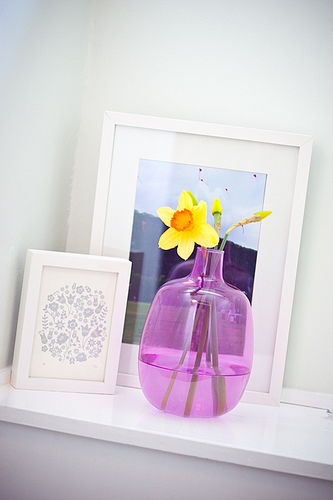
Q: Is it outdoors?
A: Yes, it is outdoors.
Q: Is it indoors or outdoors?
A: It is outdoors.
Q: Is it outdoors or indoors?
A: It is outdoors.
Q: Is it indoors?
A: No, it is outdoors.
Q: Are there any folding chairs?
A: No, there are no folding chairs.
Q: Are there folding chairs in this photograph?
A: No, there are no folding chairs.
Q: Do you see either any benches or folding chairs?
A: No, there are no folding chairs or benches.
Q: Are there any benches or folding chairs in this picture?
A: No, there are no folding chairs or benches.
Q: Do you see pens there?
A: No, there are no pens.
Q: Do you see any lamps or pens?
A: No, there are no pens or lamps.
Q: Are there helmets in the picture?
A: No, there are no helmets.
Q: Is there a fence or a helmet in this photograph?
A: No, there are no helmets or fences.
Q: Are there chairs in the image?
A: No, there are no chairs.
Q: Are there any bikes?
A: No, there are no bikes.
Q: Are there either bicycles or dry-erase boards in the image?
A: No, there are no bicycles or dry-erase boards.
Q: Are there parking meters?
A: No, there are no parking meters.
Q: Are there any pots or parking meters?
A: No, there are no parking meters or pots.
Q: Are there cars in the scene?
A: No, there are no cars.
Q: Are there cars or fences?
A: No, there are no cars or fences.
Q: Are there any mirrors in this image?
A: No, there are no mirrors.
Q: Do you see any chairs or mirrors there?
A: No, there are no mirrors or chairs.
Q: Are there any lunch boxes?
A: No, there are no lunch boxes.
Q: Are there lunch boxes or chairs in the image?
A: No, there are no lunch boxes or chairs.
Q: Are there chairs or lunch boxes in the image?
A: No, there are no lunch boxes or chairs.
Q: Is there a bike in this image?
A: No, there are no bikes.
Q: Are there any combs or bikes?
A: No, there are no bikes or combs.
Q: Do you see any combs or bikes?
A: No, there are no bikes or combs.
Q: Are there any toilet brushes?
A: No, there are no toilet brushes.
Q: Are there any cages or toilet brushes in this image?
A: No, there are no toilet brushes or cages.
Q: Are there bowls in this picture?
A: No, there are no bowls.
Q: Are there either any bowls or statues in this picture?
A: No, there are no bowls or statues.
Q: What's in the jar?
A: The water is in the jar.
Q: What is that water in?
A: The water is in the jar.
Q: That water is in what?
A: The water is in the jar.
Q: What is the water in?
A: The water is in the jar.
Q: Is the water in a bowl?
A: No, the water is in the jar.